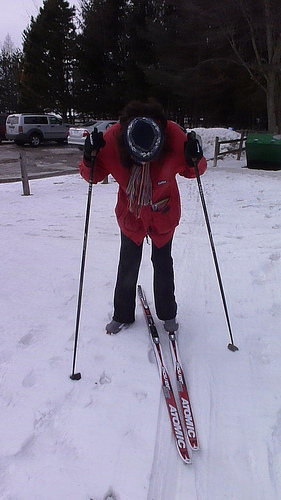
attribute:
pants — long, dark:
[98, 223, 182, 319]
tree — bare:
[136, 0, 280, 133]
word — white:
[180, 395, 198, 441]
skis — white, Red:
[138, 331, 222, 453]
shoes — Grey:
[103, 313, 186, 338]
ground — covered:
[1, 138, 280, 499]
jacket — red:
[75, 115, 209, 250]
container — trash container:
[240, 130, 280, 173]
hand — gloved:
[77, 124, 107, 176]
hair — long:
[121, 102, 178, 191]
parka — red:
[79, 120, 207, 248]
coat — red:
[66, 110, 225, 262]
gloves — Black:
[80, 128, 202, 173]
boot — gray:
[161, 313, 178, 331]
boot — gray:
[105, 318, 125, 334]